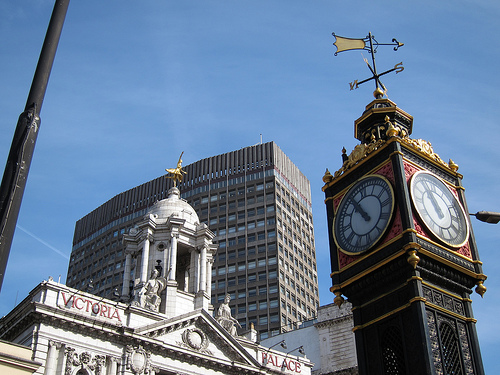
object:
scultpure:
[165, 150, 188, 187]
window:
[227, 224, 237, 234]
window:
[247, 220, 257, 230]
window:
[256, 218, 265, 228]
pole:
[0, 0, 72, 283]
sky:
[6, 0, 499, 375]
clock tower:
[323, 30, 485, 375]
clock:
[332, 175, 397, 255]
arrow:
[330, 31, 405, 55]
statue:
[216, 295, 242, 336]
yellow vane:
[332, 34, 366, 54]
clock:
[410, 170, 471, 247]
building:
[0, 25, 497, 375]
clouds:
[52, 128, 113, 150]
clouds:
[233, 51, 300, 68]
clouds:
[427, 62, 482, 89]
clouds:
[452, 135, 499, 168]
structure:
[110, 147, 220, 318]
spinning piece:
[331, 29, 405, 99]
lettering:
[60, 292, 124, 322]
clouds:
[38, 65, 160, 151]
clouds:
[137, 45, 214, 109]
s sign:
[393, 61, 404, 74]